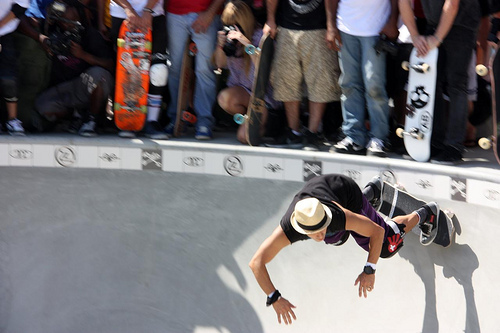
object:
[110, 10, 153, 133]
skateboard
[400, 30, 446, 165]
skateboard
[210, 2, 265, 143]
person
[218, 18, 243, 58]
camera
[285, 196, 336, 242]
hat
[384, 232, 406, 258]
logo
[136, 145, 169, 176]
design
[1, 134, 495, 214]
outer edge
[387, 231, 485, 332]
shadow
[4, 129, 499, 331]
rink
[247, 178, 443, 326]
man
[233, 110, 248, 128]
wheel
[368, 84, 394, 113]
dirt spot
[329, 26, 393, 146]
jeans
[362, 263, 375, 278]
watch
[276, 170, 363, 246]
shirt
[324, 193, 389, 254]
purple shorts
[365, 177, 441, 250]
black shoes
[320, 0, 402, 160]
man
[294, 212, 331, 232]
black line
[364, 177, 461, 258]
skateboard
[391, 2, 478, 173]
man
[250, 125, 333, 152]
sneakers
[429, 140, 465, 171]
shoe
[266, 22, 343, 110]
shorts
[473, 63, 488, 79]
wheel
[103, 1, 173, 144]
person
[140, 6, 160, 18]
band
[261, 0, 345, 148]
person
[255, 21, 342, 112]
tan shorts